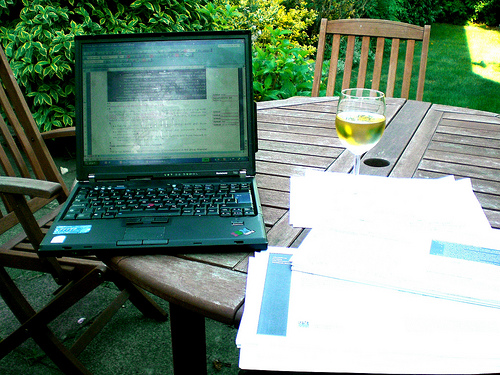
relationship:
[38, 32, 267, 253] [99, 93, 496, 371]
laptop on top of table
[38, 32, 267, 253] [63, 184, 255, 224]
laptop has keyboard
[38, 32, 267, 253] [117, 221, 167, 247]
laptop has touchpad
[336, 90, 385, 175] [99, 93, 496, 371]
glass on top of table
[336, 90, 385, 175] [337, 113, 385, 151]
glass has wine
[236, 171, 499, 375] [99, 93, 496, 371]
paper on table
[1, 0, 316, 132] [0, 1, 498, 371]
bush in backyard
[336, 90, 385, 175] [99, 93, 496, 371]
glass on table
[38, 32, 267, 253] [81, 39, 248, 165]
laptop has screen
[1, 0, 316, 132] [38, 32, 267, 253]
bush behind laptop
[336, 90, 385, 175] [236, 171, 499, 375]
glass behind paper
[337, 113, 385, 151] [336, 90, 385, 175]
wine inside glass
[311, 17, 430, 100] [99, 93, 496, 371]
chair next to table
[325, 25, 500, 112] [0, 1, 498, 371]
grass in backyard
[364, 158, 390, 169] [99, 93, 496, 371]
hole in table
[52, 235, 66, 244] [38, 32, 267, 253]
sticker on laptop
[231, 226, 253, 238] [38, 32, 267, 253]
logo on top of laptop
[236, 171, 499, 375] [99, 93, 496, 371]
paper hanging from table